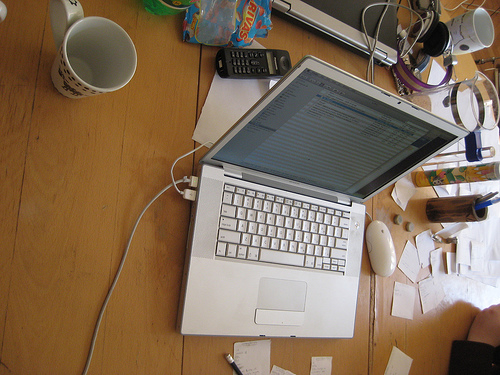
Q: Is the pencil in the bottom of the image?
A: Yes, the pencil is in the bottom of the image.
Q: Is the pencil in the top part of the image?
A: No, the pencil is in the bottom of the image.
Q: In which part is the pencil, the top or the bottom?
A: The pencil is in the bottom of the image.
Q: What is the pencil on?
A: The pencil is on the desk.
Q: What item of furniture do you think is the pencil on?
A: The pencil is on the desk.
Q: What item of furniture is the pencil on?
A: The pencil is on the desk.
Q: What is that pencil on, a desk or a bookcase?
A: The pencil is on a desk.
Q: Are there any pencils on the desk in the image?
A: Yes, there is a pencil on the desk.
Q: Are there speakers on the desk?
A: No, there is a pencil on the desk.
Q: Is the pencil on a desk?
A: Yes, the pencil is on a desk.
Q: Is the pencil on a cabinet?
A: No, the pencil is on a desk.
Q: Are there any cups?
A: Yes, there is a cup.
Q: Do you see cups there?
A: Yes, there is a cup.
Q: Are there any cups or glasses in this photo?
A: Yes, there is a cup.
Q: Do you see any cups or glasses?
A: Yes, there is a cup.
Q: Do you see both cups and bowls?
A: No, there is a cup but no bowls.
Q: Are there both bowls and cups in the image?
A: No, there is a cup but no bowls.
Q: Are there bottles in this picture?
A: No, there are no bottles.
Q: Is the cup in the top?
A: Yes, the cup is in the top of the image.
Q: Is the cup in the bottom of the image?
A: No, the cup is in the top of the image.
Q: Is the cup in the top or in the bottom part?
A: The cup is in the top of the image.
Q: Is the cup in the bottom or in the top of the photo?
A: The cup is in the top of the image.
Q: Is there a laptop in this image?
A: Yes, there is a laptop.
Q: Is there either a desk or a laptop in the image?
A: Yes, there is a laptop.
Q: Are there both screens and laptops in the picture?
A: Yes, there are both a laptop and a screen.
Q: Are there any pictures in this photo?
A: No, there are no pictures.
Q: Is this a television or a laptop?
A: This is a laptop.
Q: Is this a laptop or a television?
A: This is a laptop.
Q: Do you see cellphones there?
A: No, there are no cellphones.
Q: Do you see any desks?
A: Yes, there is a desk.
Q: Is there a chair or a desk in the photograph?
A: Yes, there is a desk.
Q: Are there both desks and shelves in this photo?
A: No, there is a desk but no shelves.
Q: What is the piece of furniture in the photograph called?
A: The piece of furniture is a desk.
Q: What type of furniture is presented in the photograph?
A: The furniture is a desk.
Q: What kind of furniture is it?
A: The piece of furniture is a desk.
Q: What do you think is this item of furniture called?
A: This is a desk.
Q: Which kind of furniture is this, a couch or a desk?
A: This is a desk.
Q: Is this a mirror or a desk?
A: This is a desk.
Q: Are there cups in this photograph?
A: Yes, there is a cup.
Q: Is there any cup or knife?
A: Yes, there is a cup.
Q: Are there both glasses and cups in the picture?
A: No, there is a cup but no glasses.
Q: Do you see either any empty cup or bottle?
A: Yes, there is an empty cup.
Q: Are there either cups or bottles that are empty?
A: Yes, the cup is empty.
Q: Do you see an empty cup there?
A: Yes, there is an empty cup.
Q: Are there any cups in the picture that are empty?
A: Yes, there is a cup that is empty.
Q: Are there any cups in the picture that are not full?
A: Yes, there is a empty cup.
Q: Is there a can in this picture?
A: No, there are no cans.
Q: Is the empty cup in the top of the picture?
A: Yes, the cup is in the top of the image.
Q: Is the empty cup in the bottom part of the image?
A: No, the cup is in the top of the image.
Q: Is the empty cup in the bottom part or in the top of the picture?
A: The cup is in the top of the image.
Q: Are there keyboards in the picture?
A: Yes, there is a keyboard.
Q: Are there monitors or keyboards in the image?
A: Yes, there is a keyboard.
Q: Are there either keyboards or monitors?
A: Yes, there is a keyboard.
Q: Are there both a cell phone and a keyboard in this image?
A: No, there is a keyboard but no cell phones.